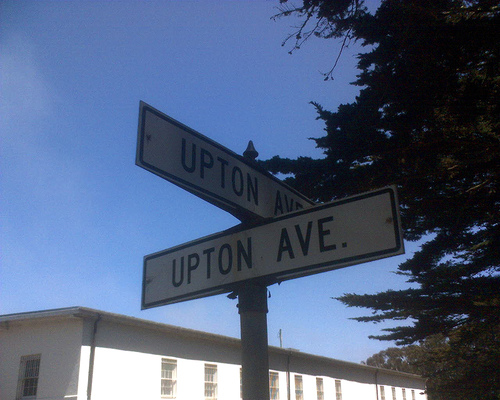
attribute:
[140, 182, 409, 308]
sign — rusty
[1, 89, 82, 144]
clouds — white  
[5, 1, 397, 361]
sky — blue 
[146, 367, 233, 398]
windows — glass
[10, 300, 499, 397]
building — white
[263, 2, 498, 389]
leaves — green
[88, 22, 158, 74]
sky — blue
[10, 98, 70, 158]
sky — blue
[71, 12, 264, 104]
sky — blue 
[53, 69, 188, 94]
sky — blue 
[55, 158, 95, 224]
sky — blue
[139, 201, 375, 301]
street sign — blue , white 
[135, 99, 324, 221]
street sign — blue , white 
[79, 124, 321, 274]
sign — white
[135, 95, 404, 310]
signs — black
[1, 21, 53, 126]
clouds — white  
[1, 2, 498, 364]
sky — blue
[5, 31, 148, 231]
clouds — white 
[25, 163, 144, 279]
clouds — white 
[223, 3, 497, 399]
trees — green 